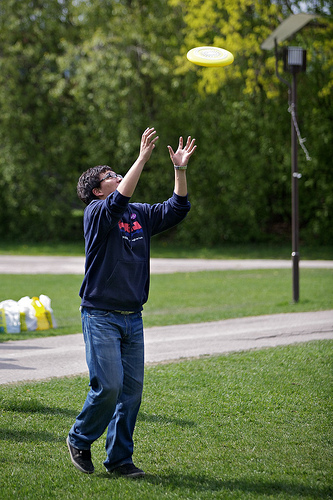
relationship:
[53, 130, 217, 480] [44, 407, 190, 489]
man wearing shoes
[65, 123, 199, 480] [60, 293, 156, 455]
man wearing jeans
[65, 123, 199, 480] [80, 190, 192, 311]
man wearing sweatshirt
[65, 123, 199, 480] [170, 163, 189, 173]
man wearing watch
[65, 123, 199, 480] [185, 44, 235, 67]
man catching frisbee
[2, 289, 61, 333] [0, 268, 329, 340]
bags in grass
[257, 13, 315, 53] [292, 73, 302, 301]
panel on pole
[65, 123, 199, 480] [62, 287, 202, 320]
man wearing belt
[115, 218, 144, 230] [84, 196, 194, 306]
writing on sweatshirt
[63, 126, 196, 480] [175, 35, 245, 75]
boy catching frisbee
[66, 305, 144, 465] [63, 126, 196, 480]
jeans worn by boy